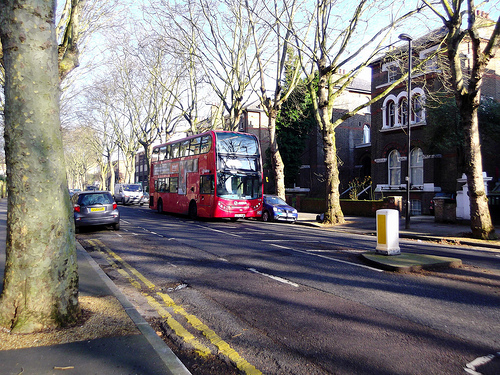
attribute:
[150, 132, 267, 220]
bus — double decker, red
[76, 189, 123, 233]
car — blue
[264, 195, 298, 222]
car — blue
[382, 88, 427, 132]
trim — white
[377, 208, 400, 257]
pole — yellow, white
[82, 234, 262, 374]
cross lines — thick, yellow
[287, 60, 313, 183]
leaves — green